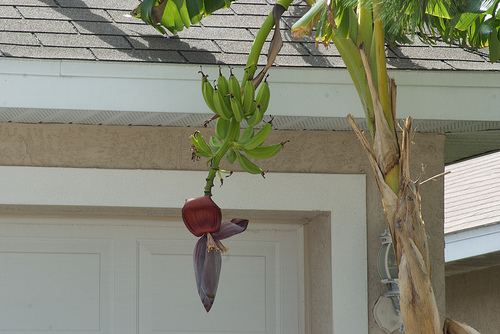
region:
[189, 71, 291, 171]
a bunch of bananas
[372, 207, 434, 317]
a light attached to the garage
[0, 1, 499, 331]
garage behind a tree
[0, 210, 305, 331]
a white garage door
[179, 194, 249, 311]
fruit flower on a tree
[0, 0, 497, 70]
roof of the garage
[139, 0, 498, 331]
a small banana tree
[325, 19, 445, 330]
a banana tree trunk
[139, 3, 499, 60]
leaves of the banana tree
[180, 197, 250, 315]
a large red fruit flower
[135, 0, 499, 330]
Banana tree with fruits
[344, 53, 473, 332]
Trunk of banana tree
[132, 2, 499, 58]
Leaves of banana tree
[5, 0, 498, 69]
Roof of a house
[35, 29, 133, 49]
Black tile of roof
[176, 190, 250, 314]
Flower of banana tree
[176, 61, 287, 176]
Two handles of banana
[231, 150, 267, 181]
Green banana on a handle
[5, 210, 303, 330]
White door of house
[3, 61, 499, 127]
Cornice of house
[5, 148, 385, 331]
Doorway on the structure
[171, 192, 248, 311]
Pink blossom on the tree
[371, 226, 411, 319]
Silver decoration on the structure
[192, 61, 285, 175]
Bananas growing on the tree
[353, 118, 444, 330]
Trunk of the tree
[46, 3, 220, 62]
Shadow on the roof of the building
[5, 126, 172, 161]
Tan portion of the building between the roof and the door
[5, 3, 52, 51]
Roof of the building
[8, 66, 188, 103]
White portion of the building just below the roof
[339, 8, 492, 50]
Leaves on the tree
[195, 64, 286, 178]
a bunch of green bananas hanging from a tree.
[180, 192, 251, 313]
A red flower below a bunch of bananas.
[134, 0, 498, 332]
A banana tree in front of a house.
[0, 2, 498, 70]
roofing tiles on a roof.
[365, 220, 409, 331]
A light on the house next to a door.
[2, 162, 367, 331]
A white door in the house with white trim.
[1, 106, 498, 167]
white perforated soffit material on the house.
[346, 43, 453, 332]
flakey brown tree bark on the trunk of a tree.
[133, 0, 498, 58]
Bright green leaves on the tree.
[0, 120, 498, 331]
the walls of the house are tan.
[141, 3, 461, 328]
Banana tree in yard.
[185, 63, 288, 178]
Green bananas on stalk.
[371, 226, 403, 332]
Light on wall of house.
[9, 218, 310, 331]
Garage door of the house.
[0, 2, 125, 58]
Shingles on roof of house.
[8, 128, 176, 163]
Beige stuccoed wall of house.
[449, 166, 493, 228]
Roof of house next door.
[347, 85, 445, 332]
Trunk of banana tree.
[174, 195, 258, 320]
A banana tree flower.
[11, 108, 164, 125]
Soffit vent of house.